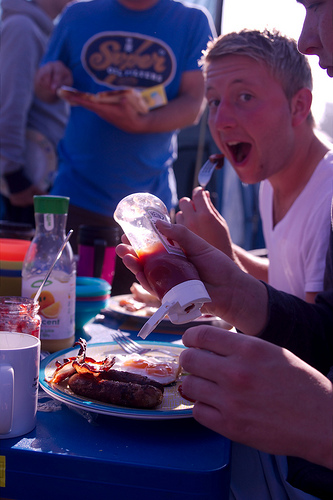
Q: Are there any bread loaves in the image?
A: No, there are no bread loaves.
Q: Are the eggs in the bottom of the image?
A: Yes, the eggs are in the bottom of the image.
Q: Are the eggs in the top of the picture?
A: No, the eggs are in the bottom of the image.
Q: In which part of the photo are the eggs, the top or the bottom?
A: The eggs are in the bottom of the image.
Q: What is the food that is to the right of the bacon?
A: The food is eggs.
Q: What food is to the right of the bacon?
A: The food is eggs.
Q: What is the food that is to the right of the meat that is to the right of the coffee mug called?
A: The food is eggs.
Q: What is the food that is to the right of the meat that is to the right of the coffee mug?
A: The food is eggs.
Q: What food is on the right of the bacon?
A: The food is eggs.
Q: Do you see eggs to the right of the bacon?
A: Yes, there are eggs to the right of the bacon.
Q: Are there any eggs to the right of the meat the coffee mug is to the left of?
A: Yes, there are eggs to the right of the bacon.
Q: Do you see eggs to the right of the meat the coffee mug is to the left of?
A: Yes, there are eggs to the right of the bacon.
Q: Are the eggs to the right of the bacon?
A: Yes, the eggs are to the right of the bacon.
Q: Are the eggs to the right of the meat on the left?
A: Yes, the eggs are to the right of the bacon.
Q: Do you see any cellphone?
A: No, there are no cell phones.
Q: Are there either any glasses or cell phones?
A: No, there are no cell phones or glasses.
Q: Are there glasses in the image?
A: No, there are no glasses.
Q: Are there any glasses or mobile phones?
A: No, there are no glasses or mobile phones.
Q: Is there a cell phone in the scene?
A: No, there are no cell phones.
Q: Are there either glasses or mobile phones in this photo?
A: No, there are no mobile phones or glasses.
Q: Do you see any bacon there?
A: Yes, there is bacon.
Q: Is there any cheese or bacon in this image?
A: Yes, there is bacon.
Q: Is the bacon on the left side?
A: Yes, the bacon is on the left of the image.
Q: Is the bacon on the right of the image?
A: No, the bacon is on the left of the image.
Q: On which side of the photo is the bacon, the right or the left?
A: The bacon is on the left of the image.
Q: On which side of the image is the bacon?
A: The bacon is on the left of the image.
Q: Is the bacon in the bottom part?
A: Yes, the bacon is in the bottom of the image.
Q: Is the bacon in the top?
A: No, the bacon is in the bottom of the image.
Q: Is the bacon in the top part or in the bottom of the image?
A: The bacon is in the bottom of the image.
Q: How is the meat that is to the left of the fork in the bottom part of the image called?
A: The meat is bacon.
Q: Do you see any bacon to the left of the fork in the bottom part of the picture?
A: Yes, there is bacon to the left of the fork.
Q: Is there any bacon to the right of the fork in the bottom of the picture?
A: No, the bacon is to the left of the fork.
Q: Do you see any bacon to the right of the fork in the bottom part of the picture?
A: No, the bacon is to the left of the fork.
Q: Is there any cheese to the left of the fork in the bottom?
A: No, there is bacon to the left of the fork.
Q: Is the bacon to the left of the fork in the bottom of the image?
A: Yes, the bacon is to the left of the fork.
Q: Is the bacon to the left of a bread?
A: No, the bacon is to the left of the fork.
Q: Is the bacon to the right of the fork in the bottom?
A: No, the bacon is to the left of the fork.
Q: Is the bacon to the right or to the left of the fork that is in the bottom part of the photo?
A: The bacon is to the left of the fork.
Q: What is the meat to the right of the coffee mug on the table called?
A: The meat is bacon.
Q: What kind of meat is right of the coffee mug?
A: The meat is bacon.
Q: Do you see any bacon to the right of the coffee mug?
A: Yes, there is bacon to the right of the coffee mug.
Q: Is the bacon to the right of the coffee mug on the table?
A: Yes, the bacon is to the right of the coffee mug.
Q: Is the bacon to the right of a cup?
A: No, the bacon is to the right of the coffee mug.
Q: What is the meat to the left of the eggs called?
A: The meat is bacon.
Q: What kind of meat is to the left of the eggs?
A: The meat is bacon.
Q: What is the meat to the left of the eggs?
A: The meat is bacon.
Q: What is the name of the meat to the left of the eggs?
A: The meat is bacon.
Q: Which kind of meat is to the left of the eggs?
A: The meat is bacon.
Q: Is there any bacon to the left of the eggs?
A: Yes, there is bacon to the left of the eggs.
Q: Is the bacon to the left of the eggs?
A: Yes, the bacon is to the left of the eggs.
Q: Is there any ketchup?
A: Yes, there is ketchup.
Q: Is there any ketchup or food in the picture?
A: Yes, there is ketchup.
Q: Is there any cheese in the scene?
A: No, there is no cheese.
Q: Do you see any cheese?
A: No, there is no cheese.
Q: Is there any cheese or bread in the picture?
A: No, there are no cheese or breads.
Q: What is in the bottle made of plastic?
A: The ketchup is in the bottle.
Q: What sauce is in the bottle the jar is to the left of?
A: The sauce is ketchup.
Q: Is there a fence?
A: No, there are no fences.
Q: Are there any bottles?
A: Yes, there is a bottle.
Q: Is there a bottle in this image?
A: Yes, there is a bottle.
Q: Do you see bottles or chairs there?
A: Yes, there is a bottle.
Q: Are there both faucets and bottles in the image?
A: No, there is a bottle but no faucets.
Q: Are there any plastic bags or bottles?
A: Yes, there is a plastic bottle.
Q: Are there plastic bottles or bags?
A: Yes, there is a plastic bottle.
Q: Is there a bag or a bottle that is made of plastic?
A: Yes, the bottle is made of plastic.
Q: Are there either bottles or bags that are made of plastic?
A: Yes, the bottle is made of plastic.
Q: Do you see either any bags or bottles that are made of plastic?
A: Yes, the bottle is made of plastic.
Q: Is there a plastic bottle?
A: Yes, there is a bottle that is made of plastic.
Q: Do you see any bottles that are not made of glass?
A: Yes, there is a bottle that is made of plastic.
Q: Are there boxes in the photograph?
A: No, there are no boxes.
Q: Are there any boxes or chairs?
A: No, there are no boxes or chairs.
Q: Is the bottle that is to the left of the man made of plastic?
A: Yes, the bottle is made of plastic.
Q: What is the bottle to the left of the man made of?
A: The bottle is made of plastic.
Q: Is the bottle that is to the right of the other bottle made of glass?
A: No, the bottle is made of plastic.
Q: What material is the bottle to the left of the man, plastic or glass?
A: The bottle is made of plastic.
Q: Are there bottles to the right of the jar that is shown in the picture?
A: Yes, there is a bottle to the right of the jar.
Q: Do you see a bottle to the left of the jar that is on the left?
A: No, the bottle is to the right of the jar.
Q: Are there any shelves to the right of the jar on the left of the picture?
A: No, there is a bottle to the right of the jar.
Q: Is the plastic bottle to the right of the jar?
A: Yes, the bottle is to the right of the jar.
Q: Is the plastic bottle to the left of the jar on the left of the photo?
A: No, the bottle is to the right of the jar.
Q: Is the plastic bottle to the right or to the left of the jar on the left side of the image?
A: The bottle is to the right of the jar.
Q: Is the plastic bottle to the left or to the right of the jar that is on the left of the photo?
A: The bottle is to the right of the jar.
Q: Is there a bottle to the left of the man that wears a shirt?
A: Yes, there is a bottle to the left of the man.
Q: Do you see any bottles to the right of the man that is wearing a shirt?
A: No, the bottle is to the left of the man.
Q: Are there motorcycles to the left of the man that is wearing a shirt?
A: No, there is a bottle to the left of the man.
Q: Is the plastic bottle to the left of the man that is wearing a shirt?
A: Yes, the bottle is to the left of the man.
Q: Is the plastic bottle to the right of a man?
A: No, the bottle is to the left of a man.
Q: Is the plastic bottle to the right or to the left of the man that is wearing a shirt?
A: The bottle is to the left of the man.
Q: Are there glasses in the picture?
A: No, there are no glasses.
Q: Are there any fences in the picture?
A: No, there are no fences.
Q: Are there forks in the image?
A: Yes, there is a fork.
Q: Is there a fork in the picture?
A: Yes, there is a fork.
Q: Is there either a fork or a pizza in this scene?
A: Yes, there is a fork.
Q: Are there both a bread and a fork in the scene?
A: No, there is a fork but no breads.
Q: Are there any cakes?
A: No, there are no cakes.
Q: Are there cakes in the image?
A: No, there are no cakes.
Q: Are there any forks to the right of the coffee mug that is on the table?
A: Yes, there is a fork to the right of the coffee mug.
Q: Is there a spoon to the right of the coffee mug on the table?
A: No, there is a fork to the right of the coffee mug.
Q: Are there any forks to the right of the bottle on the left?
A: Yes, there is a fork to the right of the bottle.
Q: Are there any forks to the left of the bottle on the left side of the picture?
A: No, the fork is to the right of the bottle.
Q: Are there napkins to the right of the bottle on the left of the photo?
A: No, there is a fork to the right of the bottle.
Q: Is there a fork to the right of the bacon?
A: Yes, there is a fork to the right of the bacon.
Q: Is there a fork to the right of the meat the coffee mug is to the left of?
A: Yes, there is a fork to the right of the bacon.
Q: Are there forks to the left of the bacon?
A: No, the fork is to the right of the bacon.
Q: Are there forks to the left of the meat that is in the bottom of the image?
A: No, the fork is to the right of the bacon.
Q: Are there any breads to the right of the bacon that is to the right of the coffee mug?
A: No, there is a fork to the right of the bacon.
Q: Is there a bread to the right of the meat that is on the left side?
A: No, there is a fork to the right of the bacon.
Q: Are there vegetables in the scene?
A: No, there are no vegetables.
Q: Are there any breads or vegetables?
A: No, there are no vegetables or breads.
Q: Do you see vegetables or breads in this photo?
A: No, there are no vegetables or breads.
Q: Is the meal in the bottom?
A: Yes, the meal is in the bottom of the image.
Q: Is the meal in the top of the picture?
A: No, the meal is in the bottom of the image.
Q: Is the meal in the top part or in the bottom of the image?
A: The meal is in the bottom of the image.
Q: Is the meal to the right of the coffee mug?
A: Yes, the meal is to the right of the coffee mug.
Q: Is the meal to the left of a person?
A: Yes, the meal is to the left of a person.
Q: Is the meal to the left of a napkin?
A: No, the meal is to the left of a person.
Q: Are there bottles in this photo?
A: Yes, there is a bottle.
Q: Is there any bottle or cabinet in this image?
A: Yes, there is a bottle.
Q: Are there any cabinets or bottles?
A: Yes, there is a bottle.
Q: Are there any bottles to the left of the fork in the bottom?
A: Yes, there is a bottle to the left of the fork.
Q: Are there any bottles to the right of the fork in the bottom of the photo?
A: No, the bottle is to the left of the fork.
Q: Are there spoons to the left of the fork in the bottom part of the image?
A: No, there is a bottle to the left of the fork.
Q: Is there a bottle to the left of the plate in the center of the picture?
A: Yes, there is a bottle to the left of the plate.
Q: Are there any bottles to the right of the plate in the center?
A: No, the bottle is to the left of the plate.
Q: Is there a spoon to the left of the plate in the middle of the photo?
A: No, there is a bottle to the left of the plate.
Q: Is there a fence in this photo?
A: No, there are no fences.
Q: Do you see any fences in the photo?
A: No, there are no fences.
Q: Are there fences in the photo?
A: No, there are no fences.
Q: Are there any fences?
A: No, there are no fences.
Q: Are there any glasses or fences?
A: No, there are no fences or glasses.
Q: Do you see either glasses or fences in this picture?
A: No, there are no fences or glasses.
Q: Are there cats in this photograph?
A: No, there are no cats.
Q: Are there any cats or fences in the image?
A: No, there are no cats or fences.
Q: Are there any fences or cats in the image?
A: No, there are no cats or fences.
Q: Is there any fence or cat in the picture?
A: No, there are no cats or fences.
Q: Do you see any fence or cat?
A: No, there are no cats or fences.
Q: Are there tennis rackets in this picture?
A: No, there are no tennis rackets.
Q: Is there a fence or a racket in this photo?
A: No, there are no rackets or fences.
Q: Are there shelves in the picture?
A: No, there are no shelves.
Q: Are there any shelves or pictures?
A: No, there are no shelves or pictures.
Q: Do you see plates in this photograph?
A: Yes, there is a plate.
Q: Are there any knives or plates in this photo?
A: Yes, there is a plate.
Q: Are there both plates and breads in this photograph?
A: No, there is a plate but no breads.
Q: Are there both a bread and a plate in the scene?
A: No, there is a plate but no breads.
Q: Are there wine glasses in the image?
A: No, there are no wine glasses.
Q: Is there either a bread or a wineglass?
A: No, there are no wine glasses or breads.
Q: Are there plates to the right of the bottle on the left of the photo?
A: Yes, there is a plate to the right of the bottle.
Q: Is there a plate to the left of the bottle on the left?
A: No, the plate is to the right of the bottle.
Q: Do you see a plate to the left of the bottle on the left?
A: No, the plate is to the right of the bottle.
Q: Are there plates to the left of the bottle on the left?
A: No, the plate is to the right of the bottle.